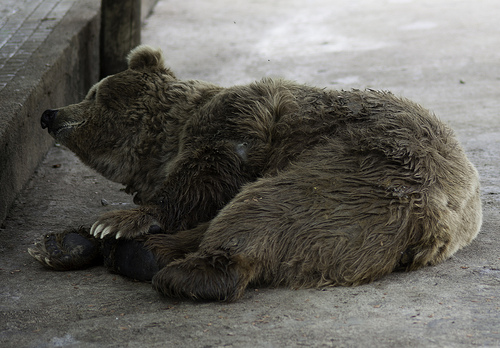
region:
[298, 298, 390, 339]
this is the ground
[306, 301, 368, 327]
the ground is clean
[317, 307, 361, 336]
the ground is grey in color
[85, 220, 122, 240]
these are the claws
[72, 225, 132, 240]
the claws are long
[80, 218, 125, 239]
the claws are sharp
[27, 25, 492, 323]
this is a bear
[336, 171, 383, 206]
the fur is rugged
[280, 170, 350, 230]
the fur is brown in color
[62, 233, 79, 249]
the paw is black in color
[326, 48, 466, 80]
this is the ground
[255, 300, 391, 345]
the ground is grey in color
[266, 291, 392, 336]
the ground is clean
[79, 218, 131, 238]
these are some claws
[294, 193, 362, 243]
the fur is rugged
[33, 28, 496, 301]
the bear is lying on the ground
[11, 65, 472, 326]
the bear is lying down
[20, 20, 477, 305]
it is brown in colour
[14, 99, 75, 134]
its mouth is black in colour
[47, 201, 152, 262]
its paws are white incolour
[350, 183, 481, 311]
the bear has no tail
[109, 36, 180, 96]
its ear is small in size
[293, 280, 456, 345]
the flor is whitish inn colour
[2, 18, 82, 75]
the floor is raised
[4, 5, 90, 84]
the floor is bricked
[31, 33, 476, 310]
a bear laying on the ground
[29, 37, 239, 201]
the head of a bear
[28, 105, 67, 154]
the nose of a bear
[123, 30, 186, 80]
the ear of a bear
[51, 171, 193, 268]
the paw of a bear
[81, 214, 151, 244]
the claws of a bear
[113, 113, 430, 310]
the back legs of a bear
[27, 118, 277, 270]
the front legs of a bear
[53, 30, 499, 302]
a big brown bear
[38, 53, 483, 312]
a big bear on the ground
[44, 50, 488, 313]
the bear is sitted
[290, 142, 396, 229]
the fur is brown in color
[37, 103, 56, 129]
this is a nose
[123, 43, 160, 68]
this is an ear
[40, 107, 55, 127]
the nose is black in color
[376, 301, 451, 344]
this is a road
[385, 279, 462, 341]
the road is clean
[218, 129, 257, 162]
this is a wound